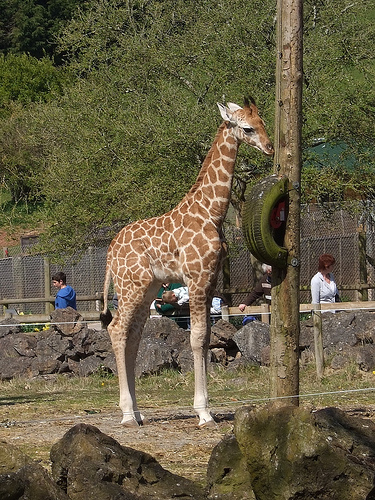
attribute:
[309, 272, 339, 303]
shirt — white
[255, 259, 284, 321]
man — older, holding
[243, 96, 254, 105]
antlers — dark, brown, giraffe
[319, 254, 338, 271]
hair — short, red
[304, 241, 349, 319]
woman — red haired, wearing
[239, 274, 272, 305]
jacket — brown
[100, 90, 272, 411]
giraffe — tall, brown and white, standing, facing right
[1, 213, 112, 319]
fence — high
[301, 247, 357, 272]
hair — red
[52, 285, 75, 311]
jacket — blue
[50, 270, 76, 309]
man — young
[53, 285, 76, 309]
sweatshirt — blue hooded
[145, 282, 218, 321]
child — small, laying face down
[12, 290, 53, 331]
post — brown, wooden, horizontal, fence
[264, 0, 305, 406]
post — wood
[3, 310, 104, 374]
stone wall — low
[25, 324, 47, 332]
flowers — yellow, green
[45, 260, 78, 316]
man — young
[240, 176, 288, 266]
tire — black, moss covered, half, green, attached, brown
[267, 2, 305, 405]
pole — tall, brown, wooden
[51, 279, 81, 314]
hoodie — blue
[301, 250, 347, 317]
female — adult